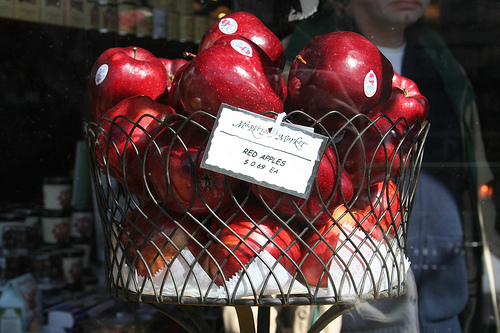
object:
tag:
[199, 103, 329, 200]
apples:
[90, 46, 168, 128]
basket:
[80, 110, 430, 306]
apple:
[285, 31, 393, 127]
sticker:
[364, 69, 378, 98]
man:
[270, 0, 500, 332]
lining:
[104, 222, 410, 300]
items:
[0, 177, 95, 284]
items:
[0, 0, 219, 45]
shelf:
[0, 17, 202, 61]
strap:
[270, 111, 286, 135]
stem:
[294, 54, 313, 69]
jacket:
[282, 18, 494, 315]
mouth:
[388, 1, 423, 10]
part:
[323, 44, 359, 59]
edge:
[317, 28, 365, 39]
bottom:
[111, 283, 408, 306]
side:
[76, 121, 120, 298]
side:
[387, 60, 394, 106]